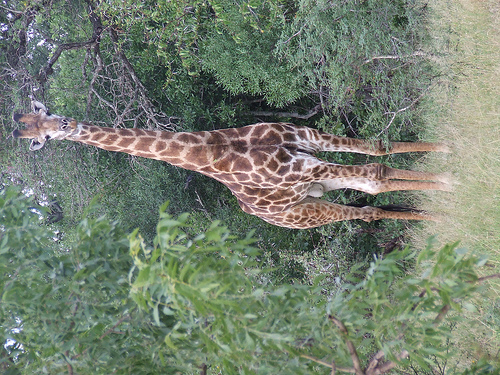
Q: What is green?
A: The trees.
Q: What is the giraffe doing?
A: Standing.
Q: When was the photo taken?
A: Day time.